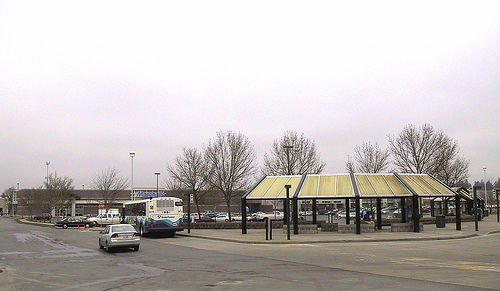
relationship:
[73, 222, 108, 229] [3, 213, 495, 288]
orange cones in street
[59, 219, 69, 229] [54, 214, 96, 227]
tire on car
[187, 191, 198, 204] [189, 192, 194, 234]
sign on pole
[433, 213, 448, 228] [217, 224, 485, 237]
garbage on sidewalk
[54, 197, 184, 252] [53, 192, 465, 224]
cars parked in parking lot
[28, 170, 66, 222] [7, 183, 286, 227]
trees planted next to building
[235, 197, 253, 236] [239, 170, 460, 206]
pole supporting roof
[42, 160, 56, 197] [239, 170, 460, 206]
light post supporting roof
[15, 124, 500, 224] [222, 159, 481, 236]
trees behind building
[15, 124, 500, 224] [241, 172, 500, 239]
trees behind bus stop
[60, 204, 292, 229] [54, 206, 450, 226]
cars in parking lot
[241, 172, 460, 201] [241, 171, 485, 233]
stand on top of bus stop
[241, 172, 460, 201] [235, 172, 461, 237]
stand on top of bus stop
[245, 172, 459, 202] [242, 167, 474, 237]
stand on top of bus stop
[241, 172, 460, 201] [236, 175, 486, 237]
stand on top of bus stop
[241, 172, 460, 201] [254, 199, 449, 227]
stand on top of bus stop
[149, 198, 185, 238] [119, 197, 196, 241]
lights on bus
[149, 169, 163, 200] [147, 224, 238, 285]
light beside street